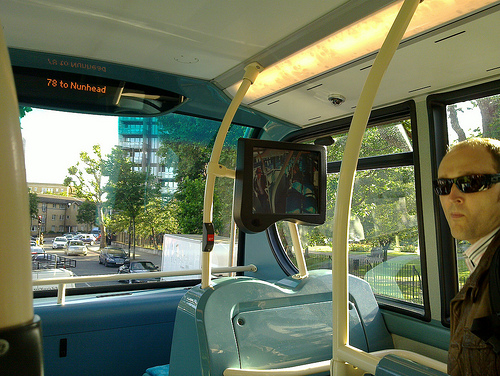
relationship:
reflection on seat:
[245, 307, 335, 362] [196, 267, 394, 374]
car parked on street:
[99, 248, 133, 269] [42, 244, 173, 283]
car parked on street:
[120, 260, 167, 285] [42, 244, 173, 283]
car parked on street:
[64, 237, 86, 258] [42, 244, 173, 283]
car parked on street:
[49, 235, 71, 252] [42, 244, 173, 283]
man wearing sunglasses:
[413, 134, 498, 370] [428, 170, 495, 197]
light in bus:
[226, 0, 498, 106] [2, 0, 499, 375]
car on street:
[51, 236, 68, 249] [41, 241, 163, 288]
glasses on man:
[431, 174, 500, 195] [433, 137, 498, 375]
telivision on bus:
[232, 137, 327, 234] [2, 0, 499, 375]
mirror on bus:
[105, 78, 192, 118] [14, 16, 426, 364]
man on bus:
[433, 137, 498, 375] [2, 0, 499, 375]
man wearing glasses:
[433, 137, 498, 375] [431, 174, 500, 195]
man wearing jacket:
[433, 137, 498, 375] [442, 227, 495, 374]